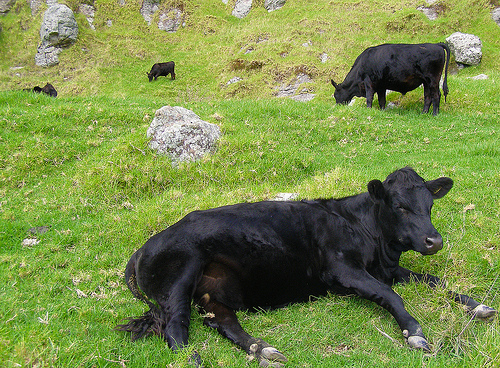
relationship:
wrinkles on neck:
[340, 207, 397, 269] [349, 187, 394, 260]